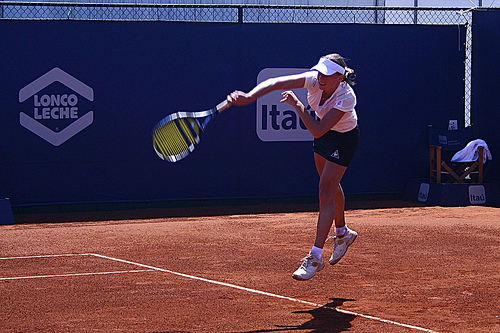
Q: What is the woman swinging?
A: A tennis racket.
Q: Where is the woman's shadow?
A: On the tennis court.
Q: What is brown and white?
A: Court.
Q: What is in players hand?
A: Racket.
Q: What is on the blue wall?
A: Sponsor logo.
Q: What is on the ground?
A: White lines.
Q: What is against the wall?
A: Blue and white chair.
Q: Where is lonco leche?
A: On wall.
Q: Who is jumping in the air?
A: Tennis player.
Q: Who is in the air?
A: Tennis player.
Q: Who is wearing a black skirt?
A: Tennis player.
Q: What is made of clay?
A: Court.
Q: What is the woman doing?
A: Swinging tennis racket.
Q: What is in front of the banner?
A: Wooden chair.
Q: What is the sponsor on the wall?
A: Lonco leche.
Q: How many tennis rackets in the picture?
A: One.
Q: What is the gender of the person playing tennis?
A: Female.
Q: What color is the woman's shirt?
A: White.